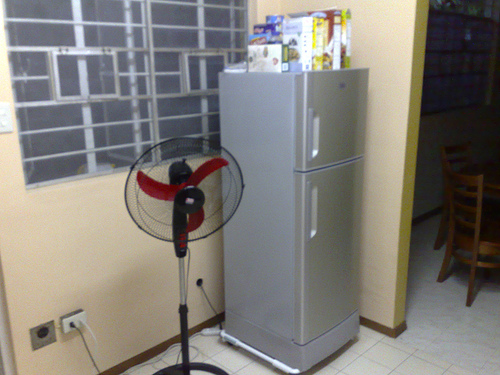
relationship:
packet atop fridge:
[282, 16, 313, 71] [217, 65, 364, 364]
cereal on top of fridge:
[280, 16, 325, 72] [212, 67, 376, 373]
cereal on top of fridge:
[272, 57, 278, 65] [212, 67, 376, 373]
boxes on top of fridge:
[247, 44, 282, 73] [212, 67, 376, 373]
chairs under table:
[436, 139, 498, 317] [461, 157, 498, 189]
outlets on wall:
[26, 306, 87, 345] [0, 0, 249, 373]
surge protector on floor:
[198, 324, 223, 338] [1, 205, 496, 372]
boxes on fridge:
[247, 44, 282, 73] [212, 67, 376, 373]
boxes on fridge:
[254, 22, 284, 42] [212, 67, 376, 373]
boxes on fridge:
[337, 7, 353, 70] [212, 67, 376, 373]